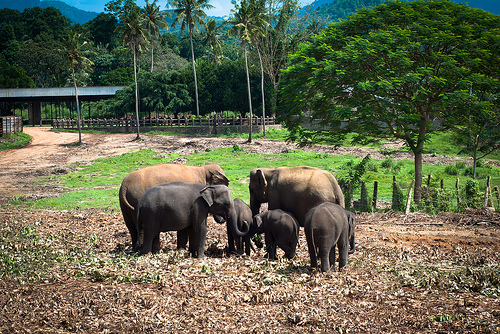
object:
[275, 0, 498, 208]
tree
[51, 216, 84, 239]
foliage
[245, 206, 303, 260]
elephant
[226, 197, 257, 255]
elephant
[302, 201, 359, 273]
elephant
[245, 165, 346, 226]
elephant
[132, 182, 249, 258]
elephant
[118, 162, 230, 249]
elephant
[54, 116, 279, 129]
fence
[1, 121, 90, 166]
road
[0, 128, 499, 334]
enclosure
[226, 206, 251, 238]
trunk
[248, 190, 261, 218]
trunk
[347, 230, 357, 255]
trunk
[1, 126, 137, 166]
dirt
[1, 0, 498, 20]
sky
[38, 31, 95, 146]
tree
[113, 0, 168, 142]
tree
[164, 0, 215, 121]
tree